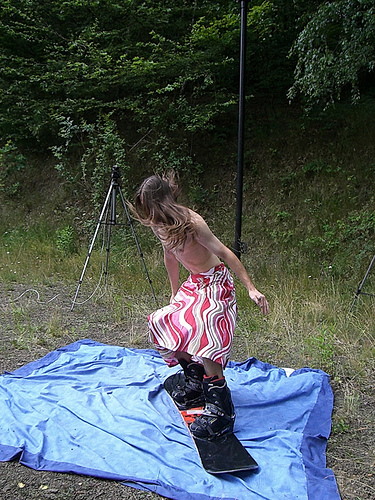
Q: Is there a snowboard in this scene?
A: Yes, there is a snowboard.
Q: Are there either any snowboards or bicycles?
A: Yes, there is a snowboard.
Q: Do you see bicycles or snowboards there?
A: Yes, there is a snowboard.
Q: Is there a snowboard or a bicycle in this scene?
A: Yes, there is a snowboard.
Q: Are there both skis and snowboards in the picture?
A: No, there is a snowboard but no skis.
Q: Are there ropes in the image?
A: No, there are no ropes.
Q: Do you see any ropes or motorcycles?
A: No, there are no ropes or motorcycles.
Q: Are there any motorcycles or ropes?
A: No, there are no ropes or motorcycles.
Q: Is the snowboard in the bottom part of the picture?
A: Yes, the snowboard is in the bottom of the image.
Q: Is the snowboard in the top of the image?
A: No, the snowboard is in the bottom of the image.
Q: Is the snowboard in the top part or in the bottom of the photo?
A: The snowboard is in the bottom of the image.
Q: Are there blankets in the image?
A: Yes, there is a blanket.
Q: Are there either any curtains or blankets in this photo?
A: Yes, there is a blanket.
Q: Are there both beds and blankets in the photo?
A: No, there is a blanket but no beds.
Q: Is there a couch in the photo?
A: No, there are no couches.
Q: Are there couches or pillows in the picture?
A: No, there are no couches or pillows.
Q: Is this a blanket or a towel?
A: This is a blanket.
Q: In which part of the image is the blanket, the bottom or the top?
A: The blanket is in the bottom of the image.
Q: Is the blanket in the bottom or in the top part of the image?
A: The blanket is in the bottom of the image.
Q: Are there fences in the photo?
A: No, there are no fences.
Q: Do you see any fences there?
A: No, there are no fences.